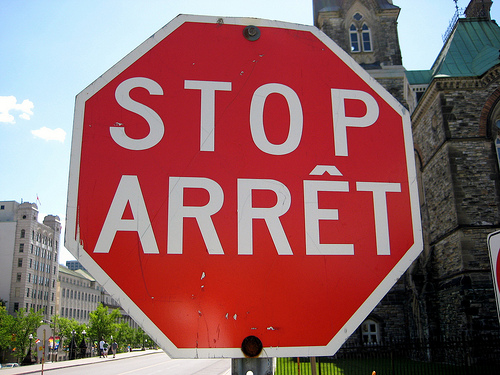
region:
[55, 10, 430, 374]
stop sign in two languages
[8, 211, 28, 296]
verticle row of windows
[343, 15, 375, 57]
two arched windows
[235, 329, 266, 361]
rusty bolt on a sign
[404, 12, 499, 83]
green roof of a building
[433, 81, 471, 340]
corner of a stone building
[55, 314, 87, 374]
tree beside a street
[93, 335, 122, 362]
people standing on a sidewalk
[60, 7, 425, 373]
red stopsign with white trim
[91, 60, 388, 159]
the word stop in white letters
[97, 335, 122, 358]
People walking on the street.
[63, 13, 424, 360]
A red and white stop sign.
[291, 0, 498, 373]
An old brick building.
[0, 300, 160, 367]
Trees lining the street.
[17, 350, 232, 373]
A gray paved roadway.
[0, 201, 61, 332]
A building in the city.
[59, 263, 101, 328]
A city building.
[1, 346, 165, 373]
A paved city sidewalk.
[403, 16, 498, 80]
A green building roof.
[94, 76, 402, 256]
White sign lettering.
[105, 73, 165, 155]
A Big White Letter "S"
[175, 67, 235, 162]
A Big White Letter "T"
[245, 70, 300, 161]
A Big White Letter "O"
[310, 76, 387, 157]
A Big White Letter "P"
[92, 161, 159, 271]
A Big White Letter "A"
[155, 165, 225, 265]
A Big White Letter "R"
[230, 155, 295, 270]
Another Big White Letter "R"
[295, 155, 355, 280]
A Big White Letter "E"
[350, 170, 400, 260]
Another Big White Letter "T"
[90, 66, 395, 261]
A stop sign saying "Stop Arret"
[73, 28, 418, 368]
a big, red STOP sign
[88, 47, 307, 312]
a big, red STOP sign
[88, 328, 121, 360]
people walking at the sidewalk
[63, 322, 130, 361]
people walking at the sidewalk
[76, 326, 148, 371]
people walking at the sidewalk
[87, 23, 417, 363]
the sign is octagon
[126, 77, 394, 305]
the sign is a stop sign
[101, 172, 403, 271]
arret is a foreign language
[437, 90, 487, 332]
the walls are made of rock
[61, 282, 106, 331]
the building has windows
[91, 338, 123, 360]
people are in pavement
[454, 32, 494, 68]
the roof is green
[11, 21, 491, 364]
it is daytime in the photo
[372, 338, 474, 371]
the fence is mettalic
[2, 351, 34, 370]
car is in the background